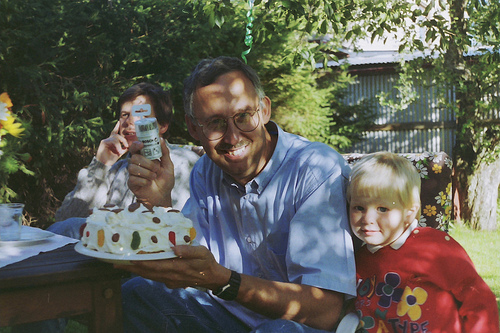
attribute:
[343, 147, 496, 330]
shirt — red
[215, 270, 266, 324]
watch — black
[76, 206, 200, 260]
cake — white frosted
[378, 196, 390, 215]
eye — baby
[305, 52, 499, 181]
shed — steel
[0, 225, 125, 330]
wooden table — brown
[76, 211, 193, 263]
cake — white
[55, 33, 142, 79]
leaves — green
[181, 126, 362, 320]
shirt — blue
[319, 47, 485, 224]
building — metal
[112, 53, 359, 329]
man — older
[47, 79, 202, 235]
woman — older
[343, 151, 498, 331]
child — blond, red, small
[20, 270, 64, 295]
wooden table — dark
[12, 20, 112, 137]
bushes — green, leafy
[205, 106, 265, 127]
eyeglasses — wire-rimmed